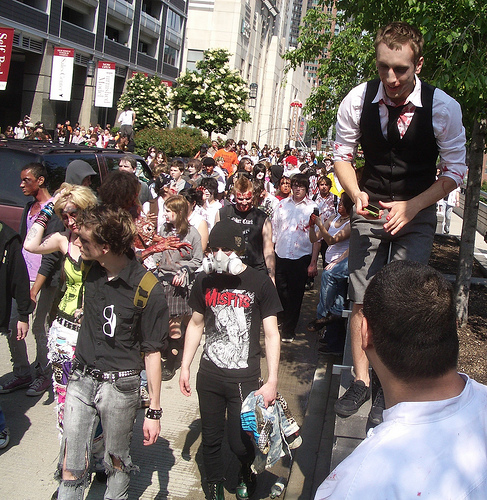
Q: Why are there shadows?
A: It is sunny.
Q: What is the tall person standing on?
A: A low wall.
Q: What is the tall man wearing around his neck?
A: A tie.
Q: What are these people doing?
A: Walking.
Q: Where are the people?
A: On the street.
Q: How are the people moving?
A: In one direction.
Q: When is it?
A: Day time.